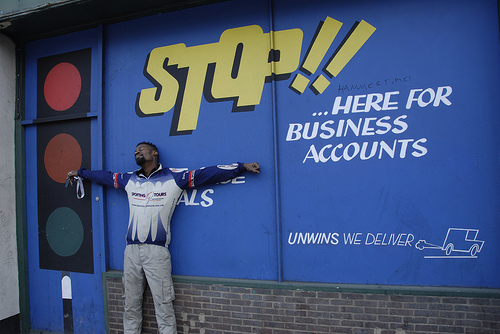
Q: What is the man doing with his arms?
A: Extending them straight out to the side of his body.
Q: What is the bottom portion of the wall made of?
A: Brick.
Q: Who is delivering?
A: UNWINS.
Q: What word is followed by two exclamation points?
A: STOP.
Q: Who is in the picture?
A: A man.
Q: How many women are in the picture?
A: Zero.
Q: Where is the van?
A: In the lower right hand corner of the sign.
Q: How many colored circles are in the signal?
A: Three.